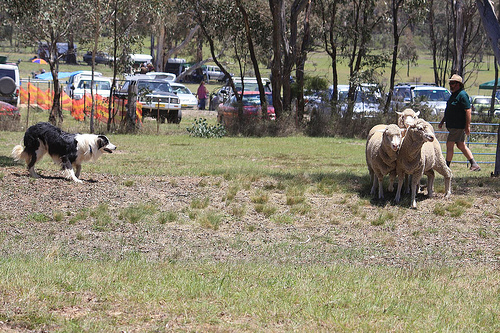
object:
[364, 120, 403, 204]
sheep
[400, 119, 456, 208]
sheep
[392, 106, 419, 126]
sheep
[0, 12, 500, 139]
trees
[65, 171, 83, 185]
paw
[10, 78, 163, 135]
fence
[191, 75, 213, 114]
person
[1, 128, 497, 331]
ground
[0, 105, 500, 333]
grass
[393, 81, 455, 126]
car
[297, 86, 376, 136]
car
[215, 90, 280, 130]
car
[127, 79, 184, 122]
car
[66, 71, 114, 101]
car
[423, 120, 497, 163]
fence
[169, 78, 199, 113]
car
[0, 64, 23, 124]
suv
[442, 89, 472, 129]
green shirt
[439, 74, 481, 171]
man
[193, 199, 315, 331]
red pole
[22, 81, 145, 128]
fabric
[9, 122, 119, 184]
dog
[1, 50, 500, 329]
field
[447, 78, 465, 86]
sunglasses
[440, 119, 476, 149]
shorts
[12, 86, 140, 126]
mesh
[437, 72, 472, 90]
hat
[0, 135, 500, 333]
area